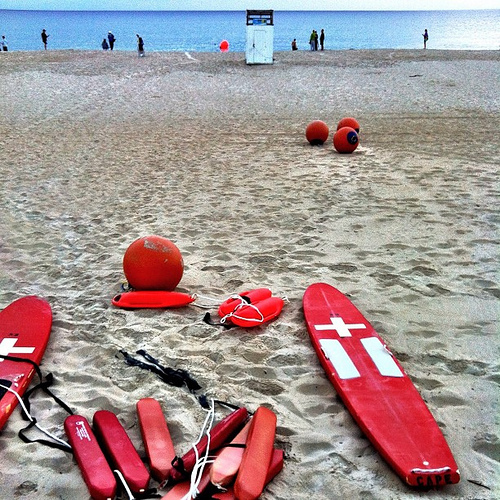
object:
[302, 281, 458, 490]
rescue board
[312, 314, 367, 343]
lifeguard cross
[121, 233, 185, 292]
buoy's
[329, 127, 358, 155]
red buoy's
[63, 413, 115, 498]
rescue equipment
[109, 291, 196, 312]
life jacket floaty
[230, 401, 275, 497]
floaties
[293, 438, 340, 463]
pile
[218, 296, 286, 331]
floating buoy's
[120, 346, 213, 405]
straps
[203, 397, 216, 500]
straps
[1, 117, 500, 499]
buoy's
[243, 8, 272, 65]
lifeguard tower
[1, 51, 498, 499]
sand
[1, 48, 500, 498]
beach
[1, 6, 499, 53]
ocean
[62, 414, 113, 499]
floaty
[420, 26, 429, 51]
peson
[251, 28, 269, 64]
door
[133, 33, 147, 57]
people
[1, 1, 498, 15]
sky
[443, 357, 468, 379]
foot prints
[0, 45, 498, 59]
shoreline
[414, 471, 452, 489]
writting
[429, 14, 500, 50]
sunlight